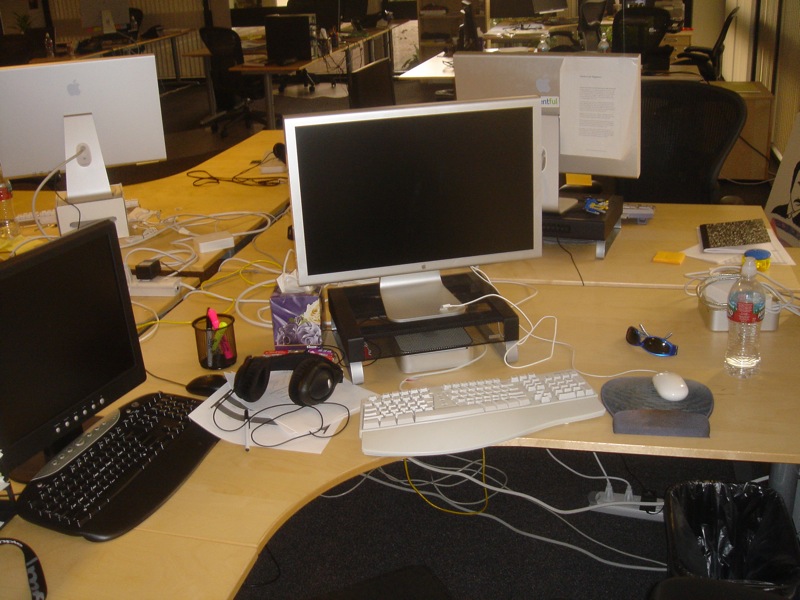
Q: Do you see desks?
A: Yes, there is a desk.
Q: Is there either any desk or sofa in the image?
A: Yes, there is a desk.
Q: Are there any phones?
A: No, there are no phones.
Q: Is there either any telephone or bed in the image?
A: No, there are no phones or beds.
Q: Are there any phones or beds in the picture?
A: No, there are no phones or beds.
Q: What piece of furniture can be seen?
A: The piece of furniture is a desk.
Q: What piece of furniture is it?
A: The piece of furniture is a desk.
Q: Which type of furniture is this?
A: This is a desk.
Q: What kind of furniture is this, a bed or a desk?
A: This is a desk.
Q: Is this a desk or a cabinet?
A: This is a desk.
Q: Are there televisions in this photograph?
A: No, there are no televisions.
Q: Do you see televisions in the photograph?
A: No, there are no televisions.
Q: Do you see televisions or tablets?
A: No, there are no televisions or tablets.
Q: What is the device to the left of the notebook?
A: The device is a monitor.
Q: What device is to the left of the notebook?
A: The device is a monitor.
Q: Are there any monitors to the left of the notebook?
A: Yes, there is a monitor to the left of the notebook.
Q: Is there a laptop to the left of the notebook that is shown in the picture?
A: No, there is a monitor to the left of the notebook.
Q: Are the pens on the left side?
A: Yes, the pens are on the left of the image.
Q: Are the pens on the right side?
A: No, the pens are on the left of the image.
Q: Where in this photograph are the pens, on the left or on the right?
A: The pens are on the left of the image.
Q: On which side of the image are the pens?
A: The pens are on the left of the image.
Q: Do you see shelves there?
A: No, there are no shelves.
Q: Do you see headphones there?
A: Yes, there are headphones.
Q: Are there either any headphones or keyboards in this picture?
A: Yes, there are headphones.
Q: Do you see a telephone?
A: No, there are no phones.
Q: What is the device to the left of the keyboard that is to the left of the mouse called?
A: The device is headphones.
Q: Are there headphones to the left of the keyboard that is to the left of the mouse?
A: Yes, there are headphones to the left of the keyboard.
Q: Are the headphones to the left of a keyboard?
A: Yes, the headphones are to the left of a keyboard.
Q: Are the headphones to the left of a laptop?
A: No, the headphones are to the left of a keyboard.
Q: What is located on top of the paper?
A: The headphones are on top of the paper.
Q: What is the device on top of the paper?
A: The device is headphones.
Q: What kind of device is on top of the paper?
A: The device is headphones.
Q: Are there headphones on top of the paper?
A: Yes, there are headphones on top of the paper.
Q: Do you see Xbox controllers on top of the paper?
A: No, there are headphones on top of the paper.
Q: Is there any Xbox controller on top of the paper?
A: No, there are headphones on top of the paper.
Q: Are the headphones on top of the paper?
A: Yes, the headphones are on top of the paper.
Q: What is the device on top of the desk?
A: The device is headphones.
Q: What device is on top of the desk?
A: The device is headphones.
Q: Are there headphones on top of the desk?
A: Yes, there are headphones on top of the desk.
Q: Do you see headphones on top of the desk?
A: Yes, there are headphones on top of the desk.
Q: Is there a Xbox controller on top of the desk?
A: No, there are headphones on top of the desk.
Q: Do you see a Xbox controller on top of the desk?
A: No, there are headphones on top of the desk.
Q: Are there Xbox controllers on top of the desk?
A: No, there are headphones on top of the desk.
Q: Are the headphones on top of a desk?
A: Yes, the headphones are on top of a desk.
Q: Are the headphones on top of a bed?
A: No, the headphones are on top of a desk.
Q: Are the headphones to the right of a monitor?
A: Yes, the headphones are to the right of a monitor.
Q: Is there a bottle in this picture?
A: Yes, there is a bottle.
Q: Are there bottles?
A: Yes, there is a bottle.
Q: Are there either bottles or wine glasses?
A: Yes, there is a bottle.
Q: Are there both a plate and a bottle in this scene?
A: No, there is a bottle but no plates.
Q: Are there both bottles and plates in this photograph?
A: No, there is a bottle but no plates.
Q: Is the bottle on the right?
A: Yes, the bottle is on the right of the image.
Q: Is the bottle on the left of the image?
A: No, the bottle is on the right of the image.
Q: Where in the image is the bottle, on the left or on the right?
A: The bottle is on the right of the image.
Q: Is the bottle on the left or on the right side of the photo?
A: The bottle is on the right of the image.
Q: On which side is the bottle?
A: The bottle is on the right of the image.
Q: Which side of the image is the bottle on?
A: The bottle is on the right of the image.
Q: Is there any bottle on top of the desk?
A: Yes, there is a bottle on top of the desk.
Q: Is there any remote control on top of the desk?
A: No, there is a bottle on top of the desk.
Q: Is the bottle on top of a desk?
A: Yes, the bottle is on top of a desk.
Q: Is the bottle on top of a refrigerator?
A: No, the bottle is on top of a desk.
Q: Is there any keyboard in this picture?
A: Yes, there is a keyboard.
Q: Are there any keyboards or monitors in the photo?
A: Yes, there is a keyboard.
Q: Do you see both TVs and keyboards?
A: No, there is a keyboard but no televisions.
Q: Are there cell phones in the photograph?
A: No, there are no cell phones.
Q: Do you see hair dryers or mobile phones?
A: No, there are no mobile phones or hair dryers.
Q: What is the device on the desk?
A: The device is a keyboard.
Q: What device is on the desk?
A: The device is a keyboard.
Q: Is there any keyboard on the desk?
A: Yes, there is a keyboard on the desk.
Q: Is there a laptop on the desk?
A: No, there is a keyboard on the desk.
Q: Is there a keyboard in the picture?
A: Yes, there is a keyboard.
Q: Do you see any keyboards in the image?
A: Yes, there is a keyboard.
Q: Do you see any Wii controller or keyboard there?
A: Yes, there is a keyboard.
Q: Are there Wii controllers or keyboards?
A: Yes, there is a keyboard.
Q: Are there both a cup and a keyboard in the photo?
A: Yes, there are both a keyboard and a cup.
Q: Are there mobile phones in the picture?
A: No, there are no mobile phones.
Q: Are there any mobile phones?
A: No, there are no mobile phones.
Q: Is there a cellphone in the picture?
A: No, there are no cell phones.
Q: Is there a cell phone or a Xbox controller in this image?
A: No, there are no cell phones or Xbox controllers.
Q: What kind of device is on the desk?
A: The device is a keyboard.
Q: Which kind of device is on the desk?
A: The device is a keyboard.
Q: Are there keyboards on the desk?
A: Yes, there is a keyboard on the desk.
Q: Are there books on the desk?
A: No, there is a keyboard on the desk.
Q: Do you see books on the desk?
A: No, there is a keyboard on the desk.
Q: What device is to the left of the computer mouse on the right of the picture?
A: The device is a keyboard.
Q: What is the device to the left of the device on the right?
A: The device is a keyboard.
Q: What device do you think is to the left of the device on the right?
A: The device is a keyboard.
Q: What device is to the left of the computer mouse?
A: The device is a keyboard.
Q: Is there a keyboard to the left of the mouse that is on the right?
A: Yes, there is a keyboard to the left of the mouse.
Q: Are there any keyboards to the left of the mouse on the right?
A: Yes, there is a keyboard to the left of the mouse.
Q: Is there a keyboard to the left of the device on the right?
A: Yes, there is a keyboard to the left of the mouse.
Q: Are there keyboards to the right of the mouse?
A: No, the keyboard is to the left of the mouse.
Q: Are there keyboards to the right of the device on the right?
A: No, the keyboard is to the left of the mouse.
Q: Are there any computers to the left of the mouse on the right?
A: No, there is a keyboard to the left of the mouse.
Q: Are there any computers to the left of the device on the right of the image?
A: No, there is a keyboard to the left of the mouse.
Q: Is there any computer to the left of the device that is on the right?
A: No, there is a keyboard to the left of the mouse.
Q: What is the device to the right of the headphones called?
A: The device is a keyboard.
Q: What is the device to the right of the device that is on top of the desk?
A: The device is a keyboard.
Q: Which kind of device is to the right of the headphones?
A: The device is a keyboard.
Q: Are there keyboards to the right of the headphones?
A: Yes, there is a keyboard to the right of the headphones.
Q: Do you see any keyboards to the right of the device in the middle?
A: Yes, there is a keyboard to the right of the headphones.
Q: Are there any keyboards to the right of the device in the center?
A: Yes, there is a keyboard to the right of the headphones.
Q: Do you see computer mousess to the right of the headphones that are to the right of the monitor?
A: No, there is a keyboard to the right of the headphones.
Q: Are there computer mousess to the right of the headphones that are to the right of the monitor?
A: No, there is a keyboard to the right of the headphones.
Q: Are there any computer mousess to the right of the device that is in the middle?
A: No, there is a keyboard to the right of the headphones.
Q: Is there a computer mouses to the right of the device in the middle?
A: No, there is a keyboard to the right of the headphones.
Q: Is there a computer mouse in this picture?
A: Yes, there is a computer mouse.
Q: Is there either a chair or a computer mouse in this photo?
A: Yes, there is a computer mouse.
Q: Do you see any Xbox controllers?
A: No, there are no Xbox controllers.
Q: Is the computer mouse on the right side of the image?
A: Yes, the computer mouse is on the right of the image.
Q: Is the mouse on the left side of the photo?
A: No, the mouse is on the right of the image.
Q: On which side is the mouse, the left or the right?
A: The mouse is on the right of the image.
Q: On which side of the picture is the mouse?
A: The mouse is on the right of the image.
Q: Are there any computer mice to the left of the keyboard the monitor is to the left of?
A: No, the computer mouse is to the right of the keyboard.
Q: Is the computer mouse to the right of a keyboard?
A: Yes, the computer mouse is to the right of a keyboard.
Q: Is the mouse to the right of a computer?
A: No, the mouse is to the right of a keyboard.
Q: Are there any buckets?
A: No, there are no buckets.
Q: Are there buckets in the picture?
A: No, there are no buckets.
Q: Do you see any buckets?
A: No, there are no buckets.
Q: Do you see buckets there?
A: No, there are no buckets.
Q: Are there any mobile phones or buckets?
A: No, there are no buckets or mobile phones.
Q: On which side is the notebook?
A: The notebook is on the right of the image.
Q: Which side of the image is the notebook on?
A: The notebook is on the right of the image.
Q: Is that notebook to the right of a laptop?
A: No, the notebook is to the right of a monitor.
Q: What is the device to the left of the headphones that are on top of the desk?
A: The device is a monitor.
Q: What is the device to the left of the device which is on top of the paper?
A: The device is a monitor.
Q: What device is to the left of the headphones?
A: The device is a monitor.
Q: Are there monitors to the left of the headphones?
A: Yes, there is a monitor to the left of the headphones.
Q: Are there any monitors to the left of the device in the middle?
A: Yes, there is a monitor to the left of the headphones.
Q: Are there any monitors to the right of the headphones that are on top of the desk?
A: No, the monitor is to the left of the headphones.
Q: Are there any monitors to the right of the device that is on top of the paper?
A: No, the monitor is to the left of the headphones.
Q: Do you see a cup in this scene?
A: Yes, there is a cup.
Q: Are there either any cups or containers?
A: Yes, there is a cup.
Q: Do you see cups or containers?
A: Yes, there is a cup.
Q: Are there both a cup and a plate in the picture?
A: No, there is a cup but no plates.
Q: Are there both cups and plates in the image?
A: No, there is a cup but no plates.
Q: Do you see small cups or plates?
A: Yes, there is a small cup.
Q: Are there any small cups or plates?
A: Yes, there is a small cup.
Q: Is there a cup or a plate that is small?
A: Yes, the cup is small.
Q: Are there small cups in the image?
A: Yes, there is a small cup.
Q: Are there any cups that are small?
A: Yes, there is a cup that is small.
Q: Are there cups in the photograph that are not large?
A: Yes, there is a small cup.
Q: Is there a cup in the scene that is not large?
A: Yes, there is a small cup.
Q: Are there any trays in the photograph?
A: No, there are no trays.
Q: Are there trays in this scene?
A: No, there are no trays.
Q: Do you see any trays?
A: No, there are no trays.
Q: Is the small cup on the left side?
A: Yes, the cup is on the left of the image.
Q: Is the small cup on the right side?
A: No, the cup is on the left of the image.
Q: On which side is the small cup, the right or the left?
A: The cup is on the left of the image.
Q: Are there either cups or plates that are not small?
A: No, there is a cup but it is small.